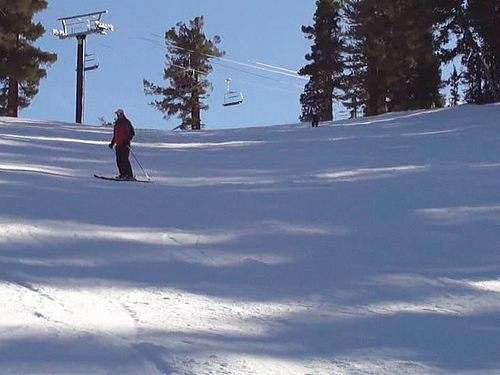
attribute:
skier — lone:
[102, 98, 143, 194]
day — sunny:
[9, 5, 498, 375]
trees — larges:
[296, 3, 500, 127]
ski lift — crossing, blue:
[36, 5, 307, 108]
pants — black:
[111, 141, 138, 177]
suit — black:
[106, 110, 134, 175]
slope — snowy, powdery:
[0, 103, 492, 368]